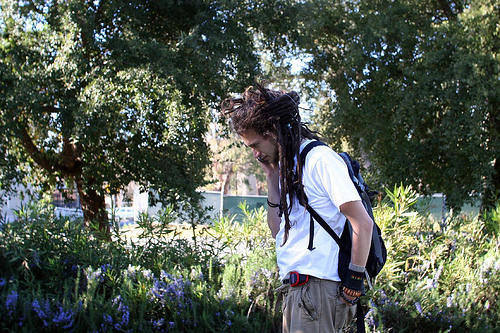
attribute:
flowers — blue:
[148, 273, 192, 311]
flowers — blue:
[99, 292, 137, 328]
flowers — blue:
[28, 300, 79, 327]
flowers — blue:
[4, 289, 19, 320]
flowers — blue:
[64, 259, 81, 276]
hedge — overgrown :
[31, 179, 221, 295]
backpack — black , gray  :
[336, 150, 385, 286]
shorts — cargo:
[281, 285, 350, 331]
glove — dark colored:
[339, 255, 371, 307]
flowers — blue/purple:
[151, 275, 193, 307]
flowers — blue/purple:
[26, 295, 75, 329]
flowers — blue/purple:
[87, 257, 132, 327]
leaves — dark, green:
[123, 104, 206, 196]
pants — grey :
[259, 272, 359, 330]